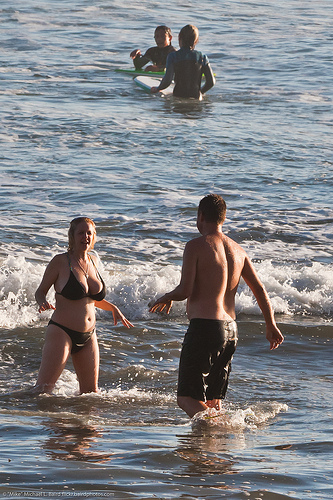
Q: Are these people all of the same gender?
A: No, they are both male and female.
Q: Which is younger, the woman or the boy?
A: The boy is younger than the woman.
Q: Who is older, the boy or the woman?
A: The woman is older than the boy.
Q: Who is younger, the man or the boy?
A: The boy is younger than the man.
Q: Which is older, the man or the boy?
A: The man is older than the boy.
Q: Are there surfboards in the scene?
A: Yes, there is a surfboard.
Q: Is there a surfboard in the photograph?
A: Yes, there is a surfboard.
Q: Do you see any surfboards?
A: Yes, there is a surfboard.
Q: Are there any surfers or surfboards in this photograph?
A: Yes, there is a surfboard.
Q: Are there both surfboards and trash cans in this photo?
A: No, there is a surfboard but no trash cans.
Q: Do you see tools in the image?
A: No, there are no tools.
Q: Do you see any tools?
A: No, there are no tools.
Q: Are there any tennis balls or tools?
A: No, there are no tools or tennis balls.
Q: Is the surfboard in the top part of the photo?
A: Yes, the surfboard is in the top of the image.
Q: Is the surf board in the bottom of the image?
A: No, the surf board is in the top of the image.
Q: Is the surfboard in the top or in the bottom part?
A: The surfboard is in the top of the image.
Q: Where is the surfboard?
A: The surfboard is in the water.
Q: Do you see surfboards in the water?
A: Yes, there is a surfboard in the water.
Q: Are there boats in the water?
A: No, there is a surfboard in the water.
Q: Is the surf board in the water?
A: Yes, the surf board is in the water.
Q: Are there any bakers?
A: No, there are no bakers.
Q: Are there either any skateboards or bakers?
A: No, there are no bakers or skateboards.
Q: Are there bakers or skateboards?
A: No, there are no bakers or skateboards.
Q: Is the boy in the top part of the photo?
A: Yes, the boy is in the top of the image.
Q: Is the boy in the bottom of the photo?
A: No, the boy is in the top of the image.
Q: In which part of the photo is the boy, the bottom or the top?
A: The boy is in the top of the image.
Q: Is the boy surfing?
A: Yes, the boy is surfing.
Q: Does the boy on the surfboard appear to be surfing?
A: Yes, the boy is surfing.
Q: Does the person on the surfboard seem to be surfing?
A: Yes, the boy is surfing.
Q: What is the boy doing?
A: The boy is surfing.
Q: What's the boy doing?
A: The boy is surfing.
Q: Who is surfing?
A: The boy is surfing.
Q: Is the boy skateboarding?
A: No, the boy is surfing.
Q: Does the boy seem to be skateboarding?
A: No, the boy is surfing.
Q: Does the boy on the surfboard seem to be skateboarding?
A: No, the boy is surfing.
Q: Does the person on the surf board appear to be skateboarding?
A: No, the boy is surfing.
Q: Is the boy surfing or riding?
A: The boy is surfing.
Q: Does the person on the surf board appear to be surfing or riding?
A: The boy is surfing.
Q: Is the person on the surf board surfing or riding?
A: The boy is surfing.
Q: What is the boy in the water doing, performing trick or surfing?
A: The boy is surfing.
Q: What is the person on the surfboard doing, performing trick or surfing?
A: The boy is surfing.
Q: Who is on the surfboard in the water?
A: The boy is on the surfboard.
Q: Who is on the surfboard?
A: The boy is on the surfboard.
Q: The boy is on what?
A: The boy is on the surfboard.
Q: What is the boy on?
A: The boy is on the surfboard.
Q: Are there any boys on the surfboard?
A: Yes, there is a boy on the surfboard.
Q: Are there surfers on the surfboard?
A: No, there is a boy on the surfboard.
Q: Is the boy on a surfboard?
A: Yes, the boy is on a surfboard.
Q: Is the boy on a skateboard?
A: No, the boy is on a surfboard.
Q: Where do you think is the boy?
A: The boy is in the water.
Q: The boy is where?
A: The boy is in the water.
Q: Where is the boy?
A: The boy is in the water.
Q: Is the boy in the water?
A: Yes, the boy is in the water.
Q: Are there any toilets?
A: No, there are no toilets.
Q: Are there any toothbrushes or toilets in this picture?
A: No, there are no toilets or toothbrushes.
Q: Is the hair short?
A: Yes, the hair is short.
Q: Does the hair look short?
A: Yes, the hair is short.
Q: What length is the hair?
A: The hair is short.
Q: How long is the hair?
A: The hair is short.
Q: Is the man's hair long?
A: No, the hair is short.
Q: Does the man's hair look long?
A: No, the hair is short.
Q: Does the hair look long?
A: No, the hair is short.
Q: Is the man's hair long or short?
A: The hair is short.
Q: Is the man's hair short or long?
A: The hair is short.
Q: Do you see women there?
A: Yes, there is a woman.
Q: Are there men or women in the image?
A: Yes, there is a woman.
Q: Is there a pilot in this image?
A: No, there are no pilots.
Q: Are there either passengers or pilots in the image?
A: No, there are no pilots or passengers.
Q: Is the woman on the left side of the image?
A: Yes, the woman is on the left of the image.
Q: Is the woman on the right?
A: No, the woman is on the left of the image.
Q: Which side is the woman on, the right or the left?
A: The woman is on the left of the image.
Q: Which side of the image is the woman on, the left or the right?
A: The woman is on the left of the image.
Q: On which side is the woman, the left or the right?
A: The woman is on the left of the image.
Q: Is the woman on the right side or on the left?
A: The woman is on the left of the image.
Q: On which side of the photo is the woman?
A: The woman is on the left of the image.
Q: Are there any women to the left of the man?
A: Yes, there is a woman to the left of the man.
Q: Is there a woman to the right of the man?
A: No, the woman is to the left of the man.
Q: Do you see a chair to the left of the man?
A: No, there is a woman to the left of the man.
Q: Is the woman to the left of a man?
A: Yes, the woman is to the left of a man.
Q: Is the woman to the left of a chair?
A: No, the woman is to the left of a man.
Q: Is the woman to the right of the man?
A: No, the woman is to the left of the man.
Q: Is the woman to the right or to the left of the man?
A: The woman is to the left of the man.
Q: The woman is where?
A: The woman is in the water.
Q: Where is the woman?
A: The woman is in the water.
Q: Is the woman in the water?
A: Yes, the woman is in the water.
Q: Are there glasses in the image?
A: No, there are no glasses.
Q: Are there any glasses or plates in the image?
A: No, there are no glasses or plates.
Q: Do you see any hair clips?
A: No, there are no hair clips.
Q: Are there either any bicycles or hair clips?
A: No, there are no hair clips or bicycles.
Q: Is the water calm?
A: Yes, the water is calm.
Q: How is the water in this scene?
A: The water is calm.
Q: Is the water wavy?
A: No, the water is calm.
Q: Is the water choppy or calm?
A: The water is calm.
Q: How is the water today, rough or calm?
A: The water is calm.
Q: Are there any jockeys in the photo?
A: No, there are no jockeys.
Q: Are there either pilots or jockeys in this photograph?
A: No, there are no jockeys or pilots.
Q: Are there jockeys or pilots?
A: No, there are no jockeys or pilots.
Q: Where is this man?
A: The man is in the water.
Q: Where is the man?
A: The man is in the water.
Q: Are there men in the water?
A: Yes, there is a man in the water.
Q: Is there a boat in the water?
A: No, there is a man in the water.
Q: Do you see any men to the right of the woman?
A: Yes, there is a man to the right of the woman.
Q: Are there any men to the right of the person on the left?
A: Yes, there is a man to the right of the woman.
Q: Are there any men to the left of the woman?
A: No, the man is to the right of the woman.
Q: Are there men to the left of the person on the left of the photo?
A: No, the man is to the right of the woman.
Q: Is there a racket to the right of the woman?
A: No, there is a man to the right of the woman.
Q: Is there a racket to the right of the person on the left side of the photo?
A: No, there is a man to the right of the woman.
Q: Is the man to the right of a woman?
A: Yes, the man is to the right of a woman.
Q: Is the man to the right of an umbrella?
A: No, the man is to the right of a woman.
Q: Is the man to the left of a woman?
A: No, the man is to the right of a woman.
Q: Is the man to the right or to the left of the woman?
A: The man is to the right of the woman.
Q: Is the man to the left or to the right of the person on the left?
A: The man is to the right of the woman.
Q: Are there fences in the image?
A: No, there are no fences.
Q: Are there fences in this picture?
A: No, there are no fences.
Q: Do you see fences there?
A: No, there are no fences.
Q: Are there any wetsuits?
A: Yes, there is a wetsuit.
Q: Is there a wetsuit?
A: Yes, there is a wetsuit.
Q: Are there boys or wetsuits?
A: Yes, there is a wetsuit.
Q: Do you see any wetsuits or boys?
A: Yes, there is a wetsuit.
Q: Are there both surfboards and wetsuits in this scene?
A: Yes, there are both a wetsuit and a surfboard.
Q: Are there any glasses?
A: No, there are no glasses.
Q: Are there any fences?
A: No, there are no fences.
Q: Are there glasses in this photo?
A: No, there are no glasses.